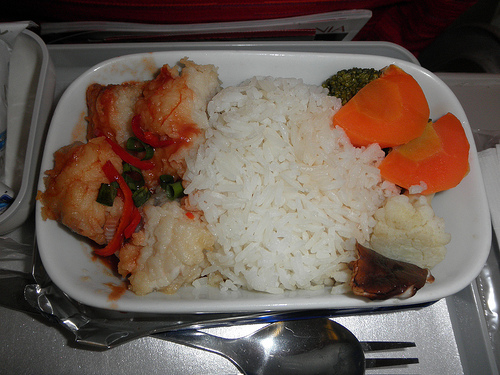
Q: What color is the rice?
A: White.